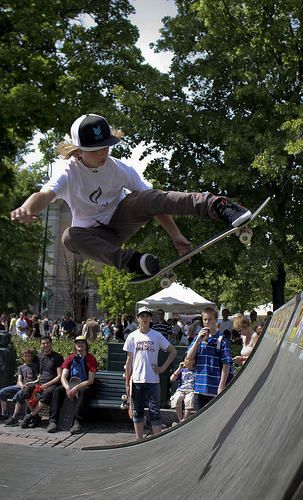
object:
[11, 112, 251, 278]
boy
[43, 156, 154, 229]
shirt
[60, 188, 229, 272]
pants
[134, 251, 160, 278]
shoes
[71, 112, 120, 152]
hat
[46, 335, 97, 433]
boy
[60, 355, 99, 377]
shirt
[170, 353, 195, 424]
man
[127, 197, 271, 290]
skateboard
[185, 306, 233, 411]
boy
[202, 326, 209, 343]
soda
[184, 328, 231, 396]
blue shirt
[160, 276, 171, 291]
wheels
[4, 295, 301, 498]
ramp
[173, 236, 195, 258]
hand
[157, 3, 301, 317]
trees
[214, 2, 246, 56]
leaves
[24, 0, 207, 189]
sky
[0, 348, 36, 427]
people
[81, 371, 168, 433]
bench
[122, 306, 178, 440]
person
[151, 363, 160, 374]
hand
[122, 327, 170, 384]
shirt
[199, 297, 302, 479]
shadow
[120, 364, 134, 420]
skateboard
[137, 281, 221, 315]
tent